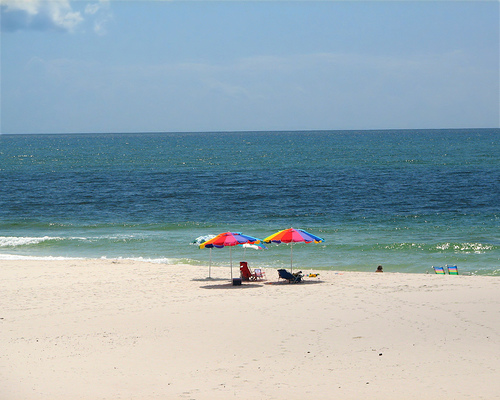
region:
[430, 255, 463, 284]
Two rainbow colored beach chairs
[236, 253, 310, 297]
Two red and blue beach chairs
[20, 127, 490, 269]
Blue and green ocean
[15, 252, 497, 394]
Light tan sandy beach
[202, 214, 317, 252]
Two rainbow colored umbrellas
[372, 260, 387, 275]
Person's head by the edge of the water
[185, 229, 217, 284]
Green and white umbrella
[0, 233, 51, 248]
White foam top of a wave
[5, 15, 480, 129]
Light blue sky above the ocean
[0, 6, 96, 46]
Puffy white cloud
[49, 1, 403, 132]
Blue sky above.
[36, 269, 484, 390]
Sandy beach.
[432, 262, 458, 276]
Brightly colored rainbow chairs.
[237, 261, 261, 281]
Red Chair.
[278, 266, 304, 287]
Black chair.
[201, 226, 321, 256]
Two matching rainbow beach umbrellas.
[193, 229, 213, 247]
One blue and white beach umbrella in the back.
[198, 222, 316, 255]
Four beach umbrellas.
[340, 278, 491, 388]
Footprints.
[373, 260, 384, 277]
Person on the beach.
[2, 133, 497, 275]
The water is choppy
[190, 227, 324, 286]
Three umbrellas on beach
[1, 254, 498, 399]
Sand on the beach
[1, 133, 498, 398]
An ocean beachfront scene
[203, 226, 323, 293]
Two umbrella are rainbow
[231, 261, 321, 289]
Two lounge chairs under umbrella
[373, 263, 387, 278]
Person is barely visible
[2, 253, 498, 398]
The sand is white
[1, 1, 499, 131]
The sky is blue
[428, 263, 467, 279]
Two chairs are near the water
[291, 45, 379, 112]
section of blue sky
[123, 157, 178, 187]
section of an ocean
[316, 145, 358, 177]
portion of sea water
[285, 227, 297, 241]
part of an umbrella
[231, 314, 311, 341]
part of a beach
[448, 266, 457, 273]
chairs on the beach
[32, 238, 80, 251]
water waves on the ocean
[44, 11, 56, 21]
section of dark clouds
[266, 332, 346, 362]
part of a white sandy beach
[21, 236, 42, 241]
ripples of water from the sea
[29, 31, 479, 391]
photo of beach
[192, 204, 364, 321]
three umbrellas on the beach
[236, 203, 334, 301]
two chairs under the umbrellas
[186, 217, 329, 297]
two of the umbrellas are the same and one is different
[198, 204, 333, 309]
brightly colored umbrellas on a beach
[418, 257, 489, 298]
chairs by the water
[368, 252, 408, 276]
a person by the water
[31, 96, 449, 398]
a sunny day at the beach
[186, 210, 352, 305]
the umbrellas cast shadows on the sand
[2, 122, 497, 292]
the ocean